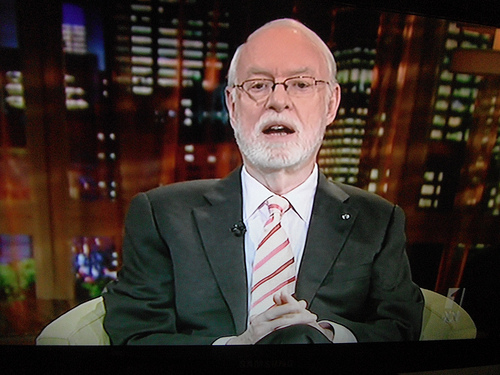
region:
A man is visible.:
[200, 189, 445, 349]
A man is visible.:
[156, 40, 425, 330]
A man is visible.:
[226, 108, 366, 256]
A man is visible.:
[166, 110, 296, 345]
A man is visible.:
[234, 145, 351, 345]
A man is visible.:
[239, 261, 342, 368]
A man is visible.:
[189, 215, 311, 370]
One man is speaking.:
[129, 49, 421, 342]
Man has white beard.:
[235, 111, 322, 170]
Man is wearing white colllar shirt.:
[235, 183, 279, 245]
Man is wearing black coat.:
[340, 250, 395, 307]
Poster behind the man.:
[19, 41, 474, 277]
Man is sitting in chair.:
[25, 297, 477, 346]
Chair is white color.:
[26, 289, 487, 341]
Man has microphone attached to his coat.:
[227, 206, 257, 247]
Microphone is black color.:
[229, 211, 252, 240]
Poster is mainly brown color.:
[18, 43, 481, 306]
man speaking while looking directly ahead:
[30, 10, 460, 336]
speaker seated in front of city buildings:
[46, 10, 472, 305]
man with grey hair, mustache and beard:
[200, 15, 350, 170]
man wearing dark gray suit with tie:
[95, 162, 420, 332]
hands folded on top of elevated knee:
[185, 305, 385, 340]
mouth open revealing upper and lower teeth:
[240, 115, 315, 145]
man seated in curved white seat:
[30, 260, 472, 337]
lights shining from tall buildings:
[335, 12, 485, 197]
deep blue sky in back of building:
[46, 7, 116, 67]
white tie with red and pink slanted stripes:
[240, 190, 301, 311]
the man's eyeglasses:
[225, 73, 337, 95]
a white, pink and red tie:
[251, 196, 301, 331]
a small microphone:
[222, 220, 250, 240]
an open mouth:
[255, 110, 307, 152]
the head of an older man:
[203, 12, 345, 192]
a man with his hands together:
[214, 267, 348, 353]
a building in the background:
[29, 4, 168, 121]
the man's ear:
[319, 77, 357, 130]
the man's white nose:
[264, 87, 296, 114]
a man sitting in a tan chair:
[111, 7, 422, 374]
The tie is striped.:
[211, 174, 328, 336]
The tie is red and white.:
[225, 185, 347, 325]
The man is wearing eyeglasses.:
[215, 67, 346, 106]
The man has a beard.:
[211, 105, 351, 177]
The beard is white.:
[212, 109, 337, 180]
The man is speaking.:
[244, 110, 315, 148]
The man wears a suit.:
[91, 157, 446, 345]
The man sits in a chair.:
[24, 12, 484, 347]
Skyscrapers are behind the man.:
[2, 2, 495, 298]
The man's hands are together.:
[202, 285, 363, 350]